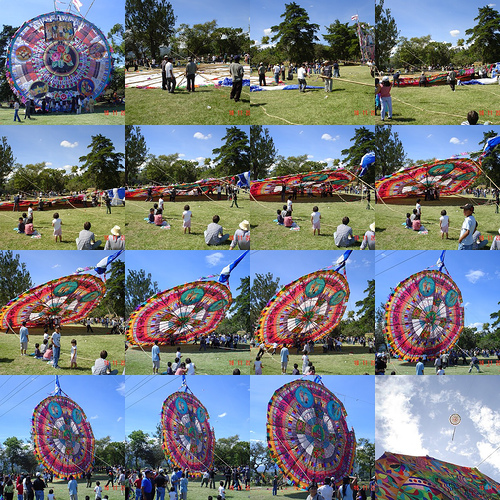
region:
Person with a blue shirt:
[66, 472, 82, 498]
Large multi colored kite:
[17, 388, 114, 485]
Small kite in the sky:
[432, 405, 464, 442]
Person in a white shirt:
[214, 477, 231, 499]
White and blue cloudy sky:
[386, 386, 455, 461]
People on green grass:
[266, 202, 349, 243]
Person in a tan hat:
[230, 220, 248, 254]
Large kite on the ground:
[136, 57, 256, 95]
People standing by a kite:
[151, 48, 244, 100]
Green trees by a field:
[271, 6, 311, 73]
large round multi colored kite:
[387, 268, 481, 382]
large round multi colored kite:
[146, 388, 239, 499]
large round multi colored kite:
[260, 386, 363, 499]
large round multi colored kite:
[271, 267, 361, 362]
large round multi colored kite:
[138, 280, 238, 372]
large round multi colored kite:
[11, 262, 111, 368]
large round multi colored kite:
[13, 15, 113, 118]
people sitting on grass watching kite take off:
[10, 145, 110, 255]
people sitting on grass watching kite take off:
[136, 145, 236, 255]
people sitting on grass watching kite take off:
[262, 138, 369, 239]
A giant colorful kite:
[21, 401, 106, 491]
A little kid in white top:
[176, 204, 196, 231]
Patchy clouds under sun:
[388, 386, 488, 457]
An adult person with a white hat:
[230, 220, 248, 247]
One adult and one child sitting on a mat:
[141, 207, 175, 227]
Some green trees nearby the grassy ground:
[128, 132, 193, 179]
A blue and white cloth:
[218, 250, 247, 285]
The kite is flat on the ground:
[130, 64, 245, 91]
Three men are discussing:
[159, 52, 198, 90]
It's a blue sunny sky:
[13, 130, 51, 151]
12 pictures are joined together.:
[52, 42, 446, 457]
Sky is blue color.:
[97, 380, 157, 405]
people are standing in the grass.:
[7, 465, 132, 496]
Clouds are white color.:
[386, 396, 403, 444]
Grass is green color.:
[140, 90, 181, 106]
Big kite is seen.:
[152, 252, 224, 352]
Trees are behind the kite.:
[10, 423, 225, 475]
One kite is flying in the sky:
[437, 406, 465, 446]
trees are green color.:
[142, 21, 234, 51]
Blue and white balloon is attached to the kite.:
[215, 255, 256, 281]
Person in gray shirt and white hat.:
[96, 216, 125, 263]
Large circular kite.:
[23, 380, 119, 477]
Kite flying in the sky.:
[428, 394, 471, 468]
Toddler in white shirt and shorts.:
[304, 193, 324, 245]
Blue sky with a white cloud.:
[422, 10, 460, 43]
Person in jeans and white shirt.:
[38, 321, 73, 358]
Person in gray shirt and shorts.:
[1, 310, 42, 362]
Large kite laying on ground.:
[397, 35, 469, 110]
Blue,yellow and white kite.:
[257, 385, 344, 493]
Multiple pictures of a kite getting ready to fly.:
[23, 33, 480, 498]